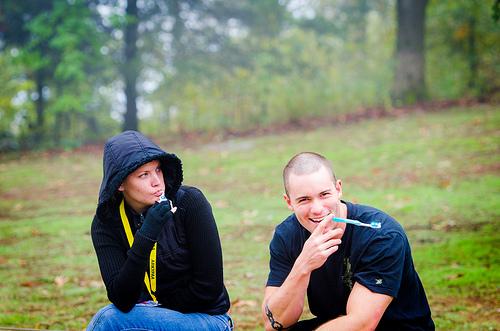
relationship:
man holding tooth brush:
[264, 151, 436, 331] [326, 212, 384, 233]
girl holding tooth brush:
[83, 132, 219, 331] [157, 195, 178, 213]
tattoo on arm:
[261, 310, 282, 330] [260, 220, 309, 331]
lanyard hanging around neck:
[117, 201, 164, 302] [119, 202, 163, 214]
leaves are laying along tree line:
[181, 94, 499, 146] [4, 4, 498, 147]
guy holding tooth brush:
[264, 151, 436, 331] [326, 212, 384, 233]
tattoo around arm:
[261, 310, 282, 330] [260, 220, 309, 331]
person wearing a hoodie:
[83, 132, 219, 331] [91, 130, 233, 317]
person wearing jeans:
[83, 132, 219, 331] [84, 303, 231, 331]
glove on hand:
[154, 198, 178, 217] [147, 196, 180, 220]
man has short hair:
[264, 151, 436, 331] [283, 152, 327, 171]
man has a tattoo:
[264, 151, 436, 331] [261, 310, 282, 330]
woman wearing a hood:
[83, 132, 219, 331] [91, 130, 182, 196]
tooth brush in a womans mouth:
[157, 195, 178, 213] [150, 188, 166, 198]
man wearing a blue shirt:
[264, 151, 436, 331] [267, 209, 436, 329]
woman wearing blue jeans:
[83, 132, 219, 331] [84, 303, 231, 331]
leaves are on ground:
[181, 94, 499, 146] [14, 115, 499, 326]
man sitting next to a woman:
[264, 151, 436, 331] [83, 132, 219, 331]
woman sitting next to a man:
[83, 132, 219, 331] [264, 151, 436, 331]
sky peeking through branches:
[34, 1, 396, 109] [140, 6, 411, 59]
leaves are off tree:
[181, 94, 499, 146] [388, 2, 433, 107]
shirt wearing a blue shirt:
[264, 151, 436, 331] [267, 209, 436, 329]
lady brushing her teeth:
[83, 132, 219, 331] [154, 191, 161, 196]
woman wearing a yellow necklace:
[83, 132, 219, 331] [117, 201, 164, 302]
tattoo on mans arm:
[261, 310, 282, 330] [260, 220, 309, 331]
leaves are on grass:
[181, 94, 499, 146] [14, 115, 499, 326]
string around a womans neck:
[117, 201, 164, 302] [119, 202, 163, 214]